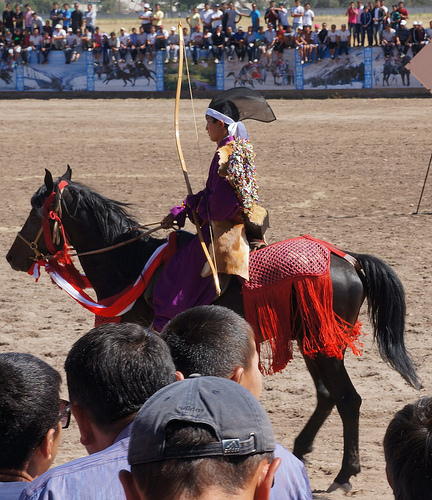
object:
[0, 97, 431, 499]
ground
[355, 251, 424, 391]
tail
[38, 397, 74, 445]
glasses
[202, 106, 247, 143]
white bandana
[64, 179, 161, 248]
mane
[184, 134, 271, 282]
dress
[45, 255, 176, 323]
ribbons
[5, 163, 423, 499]
horse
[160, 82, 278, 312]
person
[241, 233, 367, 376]
blanket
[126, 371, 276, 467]
cap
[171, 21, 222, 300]
stick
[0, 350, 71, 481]
person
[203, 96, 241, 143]
person's head